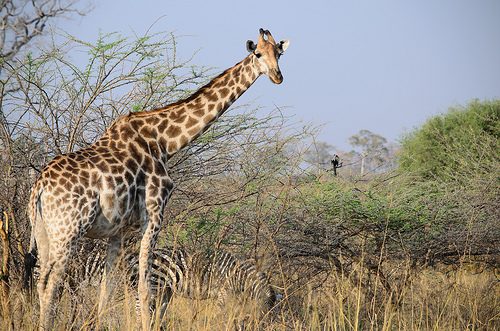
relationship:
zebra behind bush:
[131, 232, 289, 327] [169, 155, 384, 318]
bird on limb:
[327, 150, 345, 178] [326, 146, 372, 178]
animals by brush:
[19, 28, 289, 331] [197, 160, 485, 326]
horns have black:
[255, 21, 277, 51] [262, 29, 272, 37]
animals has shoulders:
[19, 28, 289, 331] [115, 115, 163, 175]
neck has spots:
[155, 58, 246, 160] [188, 102, 211, 126]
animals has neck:
[19, 28, 289, 331] [155, 58, 246, 160]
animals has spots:
[19, 28, 289, 331] [188, 102, 211, 126]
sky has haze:
[299, 2, 496, 96] [310, 6, 381, 137]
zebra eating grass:
[131, 232, 289, 327] [12, 314, 473, 330]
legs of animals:
[29, 199, 171, 323] [19, 28, 289, 331]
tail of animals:
[13, 182, 51, 279] [19, 28, 289, 331]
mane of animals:
[121, 61, 238, 117] [19, 28, 289, 331]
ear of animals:
[246, 40, 255, 53] [19, 28, 289, 331]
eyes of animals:
[254, 53, 285, 60] [19, 28, 289, 331]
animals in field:
[19, 28, 289, 331] [20, 178, 496, 326]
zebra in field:
[131, 232, 289, 327] [20, 178, 496, 326]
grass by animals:
[12, 314, 473, 330] [34, 20, 343, 315]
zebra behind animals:
[131, 232, 289, 327] [19, 28, 289, 331]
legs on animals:
[29, 199, 171, 323] [19, 28, 289, 331]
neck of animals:
[155, 58, 246, 160] [19, 28, 289, 331]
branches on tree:
[46, 55, 163, 115] [15, 24, 153, 228]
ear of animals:
[244, 36, 260, 56] [19, 28, 289, 331]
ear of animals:
[280, 38, 292, 63] [19, 28, 289, 331]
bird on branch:
[327, 150, 345, 178] [313, 148, 368, 193]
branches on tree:
[349, 127, 388, 149] [346, 126, 389, 180]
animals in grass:
[19, 28, 289, 331] [12, 314, 473, 330]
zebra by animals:
[131, 232, 289, 327] [19, 28, 289, 331]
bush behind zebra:
[181, 188, 268, 244] [131, 232, 289, 327]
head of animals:
[239, 14, 303, 91] [19, 28, 289, 331]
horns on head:
[258, 28, 276, 44] [239, 14, 303, 91]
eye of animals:
[253, 47, 263, 59] [19, 28, 289, 331]